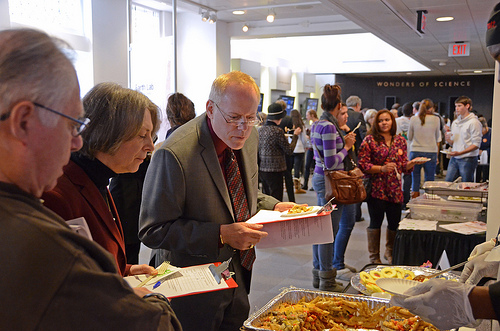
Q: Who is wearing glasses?
A: A man.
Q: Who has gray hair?
A: Old man.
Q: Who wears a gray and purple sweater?
A: A woman.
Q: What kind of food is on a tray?
A: Rice with meat.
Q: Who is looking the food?
A: Three people.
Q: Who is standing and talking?
A: A woman.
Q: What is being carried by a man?
A: Clip board.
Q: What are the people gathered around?
A: Trays of food.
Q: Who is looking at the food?
A: A man.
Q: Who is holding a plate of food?
A: A woman.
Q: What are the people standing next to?
A: Table with food.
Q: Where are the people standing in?
A: A room.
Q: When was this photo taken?
A: Inside, during the daytime.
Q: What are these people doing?
A: Getting food.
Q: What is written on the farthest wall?
A: WONDERS OF SCIENCE.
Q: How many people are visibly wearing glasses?
A: Two.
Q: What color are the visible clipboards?
A: Red.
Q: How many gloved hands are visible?
A: Three.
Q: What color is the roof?
A: White.